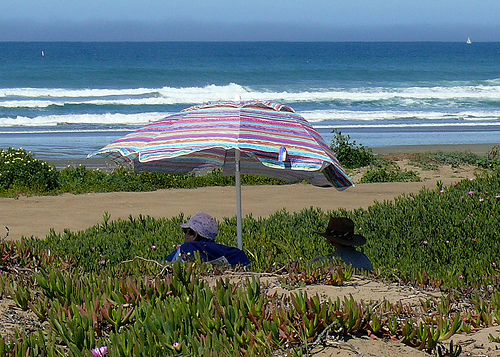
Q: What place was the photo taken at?
A: It was taken at the beach.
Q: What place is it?
A: It is a beach.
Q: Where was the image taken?
A: It was taken at the beach.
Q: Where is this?
A: This is at the beach.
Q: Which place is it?
A: It is a beach.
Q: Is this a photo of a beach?
A: Yes, it is showing a beach.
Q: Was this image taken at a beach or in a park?
A: It was taken at a beach.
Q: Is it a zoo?
A: No, it is a beach.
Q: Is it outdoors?
A: Yes, it is outdoors.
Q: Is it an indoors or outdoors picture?
A: It is outdoors.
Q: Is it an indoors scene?
A: No, it is outdoors.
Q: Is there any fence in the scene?
A: No, there are no fences.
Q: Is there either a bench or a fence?
A: No, there are no fences or benches.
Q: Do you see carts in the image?
A: No, there are no carts.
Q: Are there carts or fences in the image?
A: No, there are no carts or fences.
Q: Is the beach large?
A: Yes, the beach is large.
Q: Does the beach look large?
A: Yes, the beach is large.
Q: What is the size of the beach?
A: The beach is large.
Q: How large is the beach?
A: The beach is large.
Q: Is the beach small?
A: No, the beach is large.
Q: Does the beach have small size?
A: No, the beach is large.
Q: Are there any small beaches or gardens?
A: No, there is a beach but it is large.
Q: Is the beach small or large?
A: The beach is large.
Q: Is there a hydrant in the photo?
A: No, there are no fire hydrants.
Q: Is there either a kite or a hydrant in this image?
A: No, there are no fire hydrants or kites.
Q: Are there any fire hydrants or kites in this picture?
A: No, there are no fire hydrants or kites.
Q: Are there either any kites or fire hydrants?
A: No, there are no fire hydrants or kites.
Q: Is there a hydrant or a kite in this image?
A: No, there are no fire hydrants or kites.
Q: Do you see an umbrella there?
A: Yes, there is an umbrella.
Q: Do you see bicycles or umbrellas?
A: Yes, there is an umbrella.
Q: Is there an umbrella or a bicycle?
A: Yes, there is an umbrella.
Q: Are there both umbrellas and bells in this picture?
A: No, there is an umbrella but no bells.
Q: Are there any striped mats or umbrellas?
A: Yes, there is a striped umbrella.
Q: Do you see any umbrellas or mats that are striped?
A: Yes, the umbrella is striped.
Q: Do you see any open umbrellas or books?
A: Yes, there is an open umbrella.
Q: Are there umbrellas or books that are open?
A: Yes, the umbrella is open.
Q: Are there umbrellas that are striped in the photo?
A: Yes, there is a striped umbrella.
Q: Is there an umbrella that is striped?
A: Yes, there is an umbrella that is striped.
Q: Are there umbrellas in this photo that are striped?
A: Yes, there is an umbrella that is striped.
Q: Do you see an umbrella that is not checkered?
A: Yes, there is a striped umbrella.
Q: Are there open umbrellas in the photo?
A: Yes, there is an open umbrella.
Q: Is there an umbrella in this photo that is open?
A: Yes, there is an umbrella that is open.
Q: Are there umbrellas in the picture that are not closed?
A: Yes, there is a open umbrella.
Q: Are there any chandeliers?
A: No, there are no chandeliers.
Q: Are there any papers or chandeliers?
A: No, there are no chandeliers or papers.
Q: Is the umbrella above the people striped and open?
A: Yes, the umbrella is striped and open.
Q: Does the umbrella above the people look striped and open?
A: Yes, the umbrella is striped and open.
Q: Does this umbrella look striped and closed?
A: No, the umbrella is striped but open.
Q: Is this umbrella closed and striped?
A: No, the umbrella is striped but open.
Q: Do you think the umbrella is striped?
A: Yes, the umbrella is striped.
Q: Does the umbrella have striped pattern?
A: Yes, the umbrella is striped.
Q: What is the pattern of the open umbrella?
A: The umbrella is striped.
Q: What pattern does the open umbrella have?
A: The umbrella has striped pattern.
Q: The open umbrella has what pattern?
A: The umbrella is striped.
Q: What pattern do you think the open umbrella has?
A: The umbrella has striped pattern.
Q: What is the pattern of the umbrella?
A: The umbrella is striped.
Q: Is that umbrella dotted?
A: No, the umbrella is striped.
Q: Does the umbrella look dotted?
A: No, the umbrella is striped.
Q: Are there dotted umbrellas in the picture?
A: No, there is an umbrella but it is striped.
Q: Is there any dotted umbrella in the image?
A: No, there is an umbrella but it is striped.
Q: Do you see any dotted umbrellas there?
A: No, there is an umbrella but it is striped.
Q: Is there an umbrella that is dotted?
A: No, there is an umbrella but it is striped.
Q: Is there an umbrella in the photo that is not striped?
A: No, there is an umbrella but it is striped.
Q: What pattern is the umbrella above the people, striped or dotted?
A: The umbrella is striped.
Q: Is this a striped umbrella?
A: Yes, this is a striped umbrella.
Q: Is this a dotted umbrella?
A: No, this is a striped umbrella.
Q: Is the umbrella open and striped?
A: Yes, the umbrella is open and striped.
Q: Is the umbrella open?
A: Yes, the umbrella is open.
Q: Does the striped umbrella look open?
A: Yes, the umbrella is open.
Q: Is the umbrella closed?
A: No, the umbrella is open.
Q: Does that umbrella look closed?
A: No, the umbrella is open.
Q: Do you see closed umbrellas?
A: No, there is an umbrella but it is open.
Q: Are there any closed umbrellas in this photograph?
A: No, there is an umbrella but it is open.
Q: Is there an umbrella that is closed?
A: No, there is an umbrella but it is open.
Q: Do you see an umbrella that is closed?
A: No, there is an umbrella but it is open.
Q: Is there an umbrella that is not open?
A: No, there is an umbrella but it is open.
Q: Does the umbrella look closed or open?
A: The umbrella is open.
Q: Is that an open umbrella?
A: Yes, that is an open umbrella.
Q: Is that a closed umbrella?
A: No, that is an open umbrella.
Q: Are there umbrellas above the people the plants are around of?
A: Yes, there is an umbrella above the people.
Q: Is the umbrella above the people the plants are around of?
A: Yes, the umbrella is above the people.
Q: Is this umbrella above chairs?
A: No, the umbrella is above the people.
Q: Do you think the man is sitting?
A: Yes, the man is sitting.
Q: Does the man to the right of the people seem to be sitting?
A: Yes, the man is sitting.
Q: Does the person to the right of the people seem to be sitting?
A: Yes, the man is sitting.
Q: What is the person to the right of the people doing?
A: The man is sitting.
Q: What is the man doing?
A: The man is sitting.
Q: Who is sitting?
A: The man is sitting.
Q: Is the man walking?
A: No, the man is sitting.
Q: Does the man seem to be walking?
A: No, the man is sitting.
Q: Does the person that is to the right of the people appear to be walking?
A: No, the man is sitting.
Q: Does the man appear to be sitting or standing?
A: The man is sitting.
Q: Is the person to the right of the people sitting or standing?
A: The man is sitting.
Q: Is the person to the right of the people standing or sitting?
A: The man is sitting.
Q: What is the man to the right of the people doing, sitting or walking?
A: The man is sitting.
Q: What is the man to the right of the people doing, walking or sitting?
A: The man is sitting.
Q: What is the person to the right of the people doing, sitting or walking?
A: The man is sitting.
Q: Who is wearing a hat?
A: The man is wearing a hat.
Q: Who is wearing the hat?
A: The man is wearing a hat.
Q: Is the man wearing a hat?
A: Yes, the man is wearing a hat.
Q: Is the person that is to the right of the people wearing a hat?
A: Yes, the man is wearing a hat.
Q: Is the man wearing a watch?
A: No, the man is wearing a hat.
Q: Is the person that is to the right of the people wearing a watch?
A: No, the man is wearing a hat.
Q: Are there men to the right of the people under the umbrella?
A: Yes, there is a man to the right of the people.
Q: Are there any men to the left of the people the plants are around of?
A: No, the man is to the right of the people.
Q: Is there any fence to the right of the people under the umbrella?
A: No, there is a man to the right of the people.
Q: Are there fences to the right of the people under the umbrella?
A: No, there is a man to the right of the people.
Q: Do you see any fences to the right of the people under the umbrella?
A: No, there is a man to the right of the people.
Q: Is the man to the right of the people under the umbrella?
A: Yes, the man is to the right of the people.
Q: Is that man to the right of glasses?
A: No, the man is to the right of the people.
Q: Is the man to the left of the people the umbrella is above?
A: No, the man is to the right of the people.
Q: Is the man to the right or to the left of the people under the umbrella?
A: The man is to the right of the people.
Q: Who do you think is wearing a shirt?
A: The man is wearing a shirt.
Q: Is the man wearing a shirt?
A: Yes, the man is wearing a shirt.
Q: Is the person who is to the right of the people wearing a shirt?
A: Yes, the man is wearing a shirt.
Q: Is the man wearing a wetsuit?
A: No, the man is wearing a shirt.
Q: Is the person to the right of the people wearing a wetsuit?
A: No, the man is wearing a shirt.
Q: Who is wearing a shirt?
A: The man is wearing a shirt.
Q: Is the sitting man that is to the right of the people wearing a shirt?
A: Yes, the man is wearing a shirt.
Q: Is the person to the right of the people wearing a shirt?
A: Yes, the man is wearing a shirt.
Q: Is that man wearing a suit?
A: No, the man is wearing a shirt.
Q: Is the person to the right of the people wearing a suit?
A: No, the man is wearing a shirt.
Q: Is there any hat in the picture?
A: Yes, there is a hat.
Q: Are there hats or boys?
A: Yes, there is a hat.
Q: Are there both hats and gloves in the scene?
A: No, there is a hat but no gloves.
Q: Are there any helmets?
A: No, there are no helmets.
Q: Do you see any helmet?
A: No, there are no helmets.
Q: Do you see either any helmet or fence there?
A: No, there are no helmets or fences.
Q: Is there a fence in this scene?
A: No, there are no fences.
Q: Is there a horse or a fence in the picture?
A: No, there are no fences or horses.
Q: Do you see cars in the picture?
A: No, there are no cars.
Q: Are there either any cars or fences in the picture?
A: No, there are no cars or fences.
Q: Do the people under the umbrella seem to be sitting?
A: Yes, the people are sitting.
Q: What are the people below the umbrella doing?
A: The people are sitting.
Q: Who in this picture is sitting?
A: The people are sitting.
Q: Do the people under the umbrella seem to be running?
A: No, the people are sitting.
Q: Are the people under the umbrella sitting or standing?
A: The people are sitting.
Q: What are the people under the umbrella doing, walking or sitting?
A: The people are sitting.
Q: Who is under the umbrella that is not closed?
A: The people are under the umbrella.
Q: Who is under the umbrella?
A: The people are under the umbrella.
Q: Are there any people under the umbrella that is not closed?
A: Yes, there are people under the umbrella.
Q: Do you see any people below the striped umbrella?
A: Yes, there are people below the umbrella.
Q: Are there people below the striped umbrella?
A: Yes, there are people below the umbrella.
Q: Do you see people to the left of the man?
A: Yes, there are people to the left of the man.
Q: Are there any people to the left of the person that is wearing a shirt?
A: Yes, there are people to the left of the man.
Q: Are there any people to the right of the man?
A: No, the people are to the left of the man.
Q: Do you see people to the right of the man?
A: No, the people are to the left of the man.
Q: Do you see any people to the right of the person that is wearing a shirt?
A: No, the people are to the left of the man.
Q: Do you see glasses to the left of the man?
A: No, there are people to the left of the man.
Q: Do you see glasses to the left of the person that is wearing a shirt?
A: No, there are people to the left of the man.